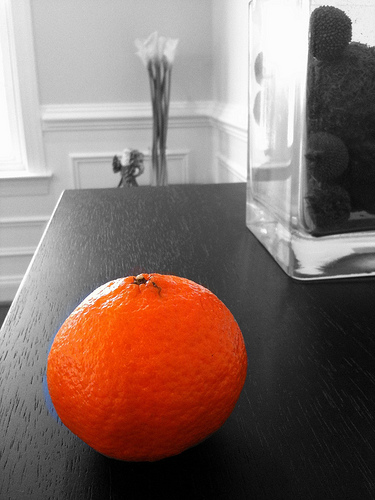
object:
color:
[49, 272, 237, 454]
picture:
[2, 0, 375, 497]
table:
[2, 182, 374, 499]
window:
[0, 0, 41, 176]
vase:
[242, 0, 374, 289]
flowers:
[136, 29, 178, 185]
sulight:
[0, 101, 20, 175]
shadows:
[58, 282, 372, 496]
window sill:
[0, 169, 57, 198]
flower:
[110, 148, 147, 186]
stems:
[145, 60, 172, 185]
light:
[17, 219, 72, 304]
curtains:
[0, 2, 38, 179]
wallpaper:
[179, 0, 244, 99]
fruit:
[40, 263, 249, 464]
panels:
[36, 177, 239, 262]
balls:
[309, 3, 354, 65]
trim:
[41, 103, 213, 126]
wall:
[13, 0, 133, 142]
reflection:
[247, 0, 307, 277]